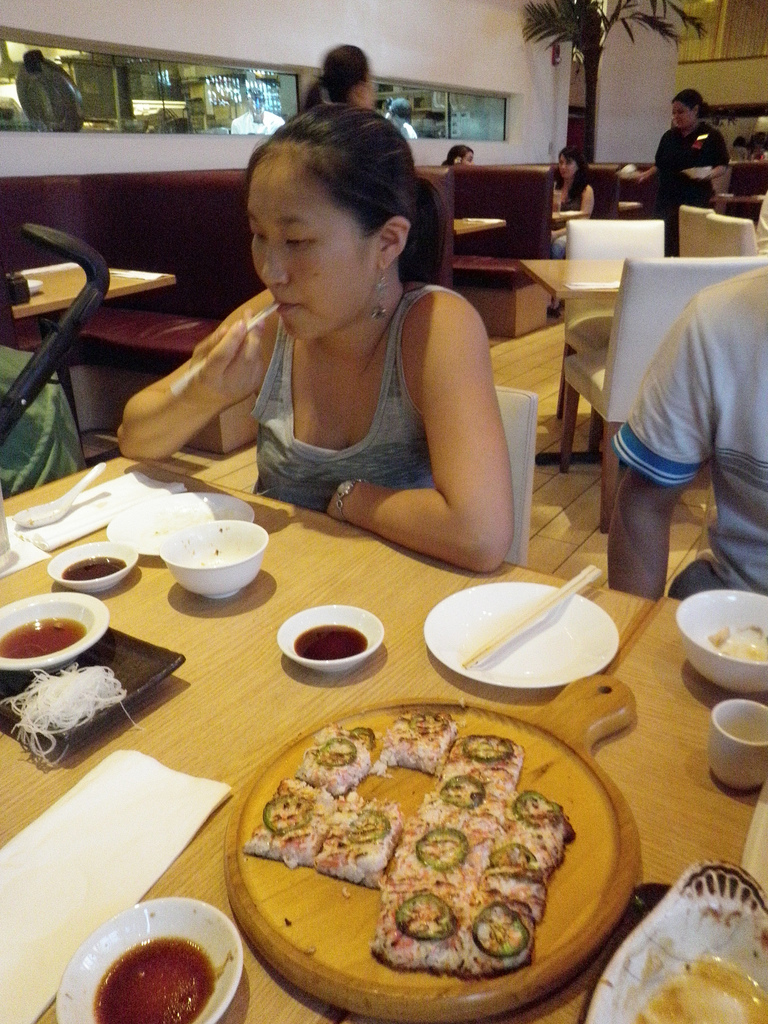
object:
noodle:
[4, 666, 138, 768]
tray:
[0, 622, 190, 751]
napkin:
[4, 747, 236, 1023]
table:
[2, 454, 763, 1023]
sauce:
[298, 625, 367, 655]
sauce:
[65, 558, 124, 578]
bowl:
[275, 600, 385, 672]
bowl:
[47, 539, 142, 593]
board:
[226, 674, 647, 1016]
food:
[241, 704, 576, 978]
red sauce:
[97, 934, 218, 1021]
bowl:
[52, 892, 246, 1018]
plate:
[422, 572, 626, 696]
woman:
[104, 91, 518, 583]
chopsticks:
[160, 295, 283, 404]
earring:
[360, 283, 396, 323]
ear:
[369, 211, 410, 275]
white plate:
[424, 589, 489, 638]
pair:
[168, 301, 276, 396]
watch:
[334, 476, 364, 523]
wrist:
[330, 479, 362, 520]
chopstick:
[460, 556, 609, 673]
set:
[455, 566, 602, 675]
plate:
[419, 580, 627, 694]